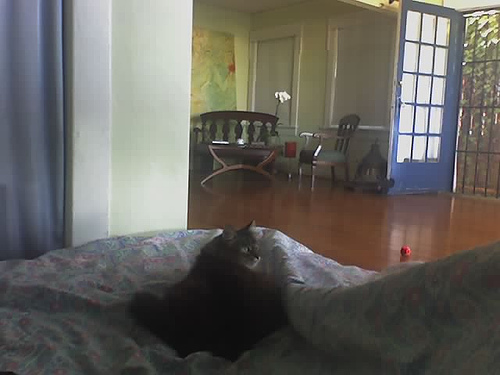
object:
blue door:
[379, 0, 467, 195]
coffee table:
[200, 142, 280, 185]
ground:
[187, 170, 500, 271]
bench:
[194, 110, 280, 175]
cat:
[125, 219, 286, 360]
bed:
[0, 226, 500, 375]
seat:
[300, 150, 345, 163]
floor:
[188, 171, 500, 272]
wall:
[110, 0, 193, 236]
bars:
[451, 9, 500, 198]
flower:
[274, 90, 291, 103]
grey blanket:
[0, 227, 500, 375]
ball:
[399, 245, 411, 256]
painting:
[189, 26, 238, 143]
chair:
[297, 114, 360, 193]